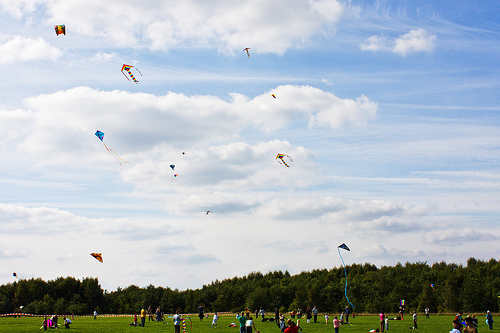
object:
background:
[0, 0, 499, 332]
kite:
[88, 252, 105, 262]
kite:
[93, 129, 129, 169]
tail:
[337, 247, 356, 308]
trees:
[246, 285, 271, 312]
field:
[0, 314, 499, 332]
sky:
[0, 0, 500, 294]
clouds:
[358, 29, 438, 58]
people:
[58, 314, 74, 327]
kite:
[44, 319, 55, 329]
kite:
[179, 150, 184, 155]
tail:
[103, 140, 125, 170]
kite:
[54, 23, 66, 36]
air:
[290, 0, 498, 76]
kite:
[241, 47, 251, 59]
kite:
[168, 163, 176, 171]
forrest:
[0, 257, 499, 315]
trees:
[82, 278, 106, 313]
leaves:
[473, 276, 477, 281]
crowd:
[1, 303, 499, 332]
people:
[210, 311, 219, 327]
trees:
[440, 274, 459, 313]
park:
[0, 310, 499, 332]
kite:
[121, 63, 143, 86]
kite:
[272, 152, 296, 170]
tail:
[281, 158, 293, 169]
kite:
[337, 242, 356, 308]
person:
[236, 310, 246, 332]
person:
[208, 310, 220, 327]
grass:
[0, 312, 500, 333]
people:
[311, 305, 318, 323]